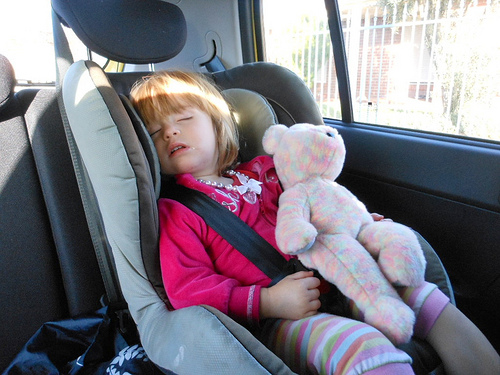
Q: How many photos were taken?
A: 2.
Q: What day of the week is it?
A: Tuesday.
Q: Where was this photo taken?
A: The family car.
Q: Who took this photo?
A: The mother.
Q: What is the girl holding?
A: A teddy bear.